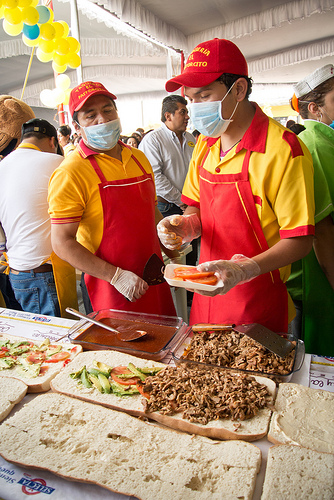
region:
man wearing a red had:
[75, 71, 157, 313]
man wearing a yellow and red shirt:
[83, 74, 171, 262]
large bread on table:
[45, 396, 237, 498]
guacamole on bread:
[80, 357, 139, 399]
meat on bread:
[162, 368, 270, 430]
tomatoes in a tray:
[164, 253, 218, 301]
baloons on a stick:
[16, 4, 78, 79]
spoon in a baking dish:
[66, 305, 157, 349]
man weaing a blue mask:
[167, 32, 298, 248]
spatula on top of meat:
[194, 319, 295, 356]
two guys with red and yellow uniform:
[52, 41, 304, 344]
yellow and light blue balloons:
[0, 1, 83, 72]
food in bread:
[4, 338, 277, 393]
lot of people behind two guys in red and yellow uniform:
[0, 54, 332, 307]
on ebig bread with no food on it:
[0, 441, 268, 473]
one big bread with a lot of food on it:
[67, 363, 266, 423]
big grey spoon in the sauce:
[56, 295, 149, 345]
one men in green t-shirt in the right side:
[285, 77, 333, 352]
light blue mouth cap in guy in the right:
[184, 75, 256, 140]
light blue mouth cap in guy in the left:
[78, 120, 129, 144]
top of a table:
[320, 362, 321, 364]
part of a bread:
[145, 444, 165, 467]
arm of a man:
[96, 265, 104, 274]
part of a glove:
[210, 110, 216, 121]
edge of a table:
[18, 482, 39, 492]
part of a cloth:
[224, 198, 227, 211]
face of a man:
[314, 373, 329, 383]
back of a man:
[41, 125, 48, 136]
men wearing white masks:
[63, 57, 293, 173]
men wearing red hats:
[50, 49, 269, 123]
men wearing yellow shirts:
[49, 113, 331, 281]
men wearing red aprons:
[62, 108, 266, 319]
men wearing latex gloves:
[89, 235, 283, 297]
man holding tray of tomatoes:
[152, 220, 228, 311]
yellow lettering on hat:
[65, 77, 129, 116]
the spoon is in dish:
[53, 291, 163, 360]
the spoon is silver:
[60, 302, 168, 354]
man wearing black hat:
[9, 105, 82, 167]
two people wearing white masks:
[42, 61, 242, 134]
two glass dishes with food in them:
[73, 279, 313, 397]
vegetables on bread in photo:
[75, 344, 163, 406]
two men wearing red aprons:
[52, 107, 292, 298]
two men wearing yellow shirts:
[60, 97, 322, 239]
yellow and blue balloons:
[10, 7, 110, 91]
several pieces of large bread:
[6, 320, 329, 495]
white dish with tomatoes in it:
[152, 231, 238, 296]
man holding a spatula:
[107, 246, 183, 293]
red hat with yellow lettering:
[156, 39, 244, 92]